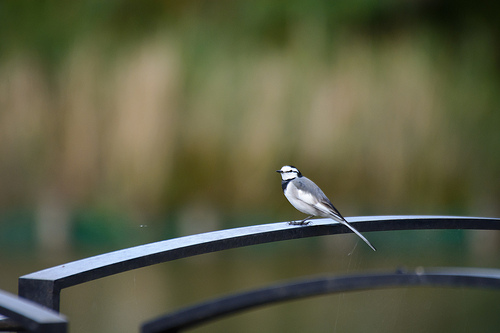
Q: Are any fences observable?
A: Yes, there is a fence.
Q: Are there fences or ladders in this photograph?
A: Yes, there is a fence.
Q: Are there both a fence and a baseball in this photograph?
A: No, there is a fence but no baseballs.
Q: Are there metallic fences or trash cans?
A: Yes, there is a metal fence.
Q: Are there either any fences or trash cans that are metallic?
A: Yes, the fence is metallic.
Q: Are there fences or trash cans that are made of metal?
A: Yes, the fence is made of metal.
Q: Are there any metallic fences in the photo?
A: Yes, there is a metal fence.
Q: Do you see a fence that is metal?
A: Yes, there is a metal fence.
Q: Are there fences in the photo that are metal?
A: Yes, there is a metal fence.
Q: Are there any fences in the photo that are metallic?
A: Yes, there is a fence that is metallic.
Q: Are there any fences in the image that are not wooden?
A: Yes, there is a metallic fence.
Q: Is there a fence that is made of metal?
A: Yes, there is a fence that is made of metal.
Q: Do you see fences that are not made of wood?
A: Yes, there is a fence that is made of metal.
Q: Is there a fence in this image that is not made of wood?
A: Yes, there is a fence that is made of metal.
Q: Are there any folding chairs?
A: No, there are no folding chairs.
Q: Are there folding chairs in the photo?
A: No, there are no folding chairs.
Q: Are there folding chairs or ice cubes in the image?
A: No, there are no folding chairs or ice cubes.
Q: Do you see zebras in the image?
A: No, there are no zebras.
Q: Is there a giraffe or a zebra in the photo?
A: No, there are no zebras or giraffes.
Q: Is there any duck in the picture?
A: No, there are no ducks.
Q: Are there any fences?
A: Yes, there is a fence.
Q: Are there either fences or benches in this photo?
A: Yes, there is a fence.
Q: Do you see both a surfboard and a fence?
A: No, there is a fence but no surfboards.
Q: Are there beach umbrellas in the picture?
A: No, there are no beach umbrellas.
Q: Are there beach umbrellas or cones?
A: No, there are no beach umbrellas or cones.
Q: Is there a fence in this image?
A: Yes, there is a fence.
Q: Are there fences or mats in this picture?
A: Yes, there is a fence.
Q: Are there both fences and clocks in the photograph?
A: No, there is a fence but no clocks.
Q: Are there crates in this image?
A: No, there are no crates.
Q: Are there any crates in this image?
A: No, there are no crates.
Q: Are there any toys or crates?
A: No, there are no crates or toys.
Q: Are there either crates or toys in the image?
A: No, there are no crates or toys.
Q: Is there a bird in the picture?
A: Yes, there is a bird.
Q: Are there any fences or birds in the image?
A: Yes, there is a bird.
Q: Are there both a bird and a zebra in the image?
A: No, there is a bird but no zebras.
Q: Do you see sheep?
A: No, there are no sheep.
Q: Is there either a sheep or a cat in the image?
A: No, there are no sheep or cats.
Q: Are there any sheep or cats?
A: No, there are no sheep or cats.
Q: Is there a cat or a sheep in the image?
A: No, there are no sheep or cats.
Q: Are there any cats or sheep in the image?
A: No, there are no sheep or cats.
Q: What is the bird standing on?
A: The bird is standing on the fence.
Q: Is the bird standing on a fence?
A: Yes, the bird is standing on a fence.